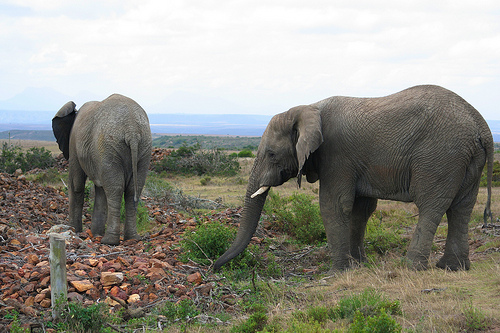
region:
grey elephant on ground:
[172, 86, 498, 279]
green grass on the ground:
[353, 311, 381, 330]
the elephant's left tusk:
[251, 183, 272, 200]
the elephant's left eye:
[262, 147, 276, 164]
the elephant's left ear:
[298, 105, 323, 177]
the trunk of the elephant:
[212, 160, 265, 268]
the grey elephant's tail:
[477, 122, 495, 234]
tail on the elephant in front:
[123, 130, 148, 211]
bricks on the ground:
[81, 255, 136, 296]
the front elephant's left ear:
[53, 96, 78, 164]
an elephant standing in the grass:
[241, 77, 498, 312]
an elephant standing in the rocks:
[32, 95, 159, 245]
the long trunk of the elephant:
[229, 151, 271, 288]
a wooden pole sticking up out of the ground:
[44, 225, 89, 322]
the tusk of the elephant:
[253, 184, 273, 199]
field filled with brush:
[161, 134, 271, 259]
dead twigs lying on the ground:
[134, 275, 228, 326]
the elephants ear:
[296, 102, 330, 199]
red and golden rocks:
[75, 254, 147, 313]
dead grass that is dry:
[363, 257, 473, 329]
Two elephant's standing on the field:
[47, 84, 488, 276]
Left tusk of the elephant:
[248, 183, 271, 199]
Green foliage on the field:
[157, 139, 238, 176]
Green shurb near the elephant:
[178, 222, 260, 268]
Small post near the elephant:
[44, 224, 70, 319]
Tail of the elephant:
[483, 146, 493, 224]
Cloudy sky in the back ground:
[2, 0, 499, 117]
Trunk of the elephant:
[206, 182, 265, 272]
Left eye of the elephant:
[264, 149, 276, 159]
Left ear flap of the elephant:
[287, 104, 324, 191]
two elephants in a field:
[46, 76, 498, 278]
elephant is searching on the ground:
[191, 76, 498, 298]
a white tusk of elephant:
[247, 182, 271, 201]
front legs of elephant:
[316, 185, 381, 275]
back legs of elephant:
[402, 202, 477, 276]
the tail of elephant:
[480, 138, 497, 232]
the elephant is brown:
[41, 87, 161, 242]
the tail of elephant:
[121, 130, 149, 205]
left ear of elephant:
[43, 94, 82, 165]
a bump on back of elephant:
[302, 88, 372, 110]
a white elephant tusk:
[248, 185, 270, 198]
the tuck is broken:
[249, 183, 269, 200]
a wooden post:
[44, 235, 68, 310]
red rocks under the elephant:
[0, 181, 202, 310]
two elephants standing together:
[54, 84, 494, 266]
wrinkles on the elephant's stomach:
[389, 145, 414, 191]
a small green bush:
[179, 221, 248, 266]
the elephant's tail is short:
[127, 135, 138, 200]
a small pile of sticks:
[484, 220, 499, 237]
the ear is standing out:
[52, 102, 77, 150]